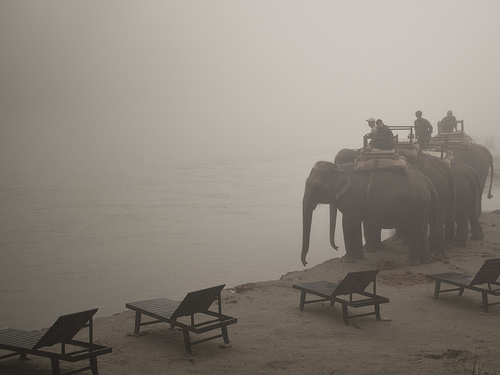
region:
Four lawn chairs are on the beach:
[25, 260, 491, 368]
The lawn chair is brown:
[253, 237, 388, 332]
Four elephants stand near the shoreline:
[304, 84, 485, 266]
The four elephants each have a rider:
[314, 90, 488, 272]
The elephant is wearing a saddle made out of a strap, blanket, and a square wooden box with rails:
[329, 110, 422, 222]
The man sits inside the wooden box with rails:
[321, 108, 404, 179]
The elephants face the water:
[83, 42, 458, 279]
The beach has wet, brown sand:
[185, 212, 477, 362]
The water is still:
[28, 48, 304, 271]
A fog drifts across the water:
[29, 19, 465, 239]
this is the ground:
[243, 297, 278, 371]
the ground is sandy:
[254, 297, 289, 367]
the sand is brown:
[248, 295, 283, 370]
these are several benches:
[5, 281, 236, 370]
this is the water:
[38, 218, 173, 288]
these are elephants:
[308, 105, 491, 260]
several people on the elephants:
[366, 111, 453, 163]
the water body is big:
[76, 70, 262, 241]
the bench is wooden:
[148, 297, 172, 311]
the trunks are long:
[300, 192, 337, 262]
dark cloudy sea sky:
[30, 42, 175, 192]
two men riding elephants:
[352, 109, 399, 149]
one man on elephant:
[411, 96, 433, 141]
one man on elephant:
[443, 113, 464, 131]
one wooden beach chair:
[8, 303, 130, 370]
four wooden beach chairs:
[19, 241, 494, 371]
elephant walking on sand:
[296, 161, 466, 250]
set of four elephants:
[336, 116, 498, 237]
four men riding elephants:
[354, 114, 481, 178]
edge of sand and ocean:
[228, 262, 303, 345]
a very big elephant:
[288, 149, 432, 269]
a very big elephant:
[371, 125, 473, 245]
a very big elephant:
[406, 115, 499, 228]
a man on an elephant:
[366, 117, 396, 152]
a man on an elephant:
[360, 112, 377, 134]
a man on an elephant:
[409, 106, 434, 143]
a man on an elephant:
[437, 102, 461, 134]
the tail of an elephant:
[485, 152, 498, 199]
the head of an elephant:
[296, 141, 336, 265]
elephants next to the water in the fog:
[29, 5, 493, 373]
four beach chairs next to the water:
[10, 251, 497, 362]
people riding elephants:
[289, 101, 493, 284]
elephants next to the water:
[283, 104, 493, 276]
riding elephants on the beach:
[281, 104, 498, 276]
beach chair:
[290, 266, 410, 340]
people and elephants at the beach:
[7, 59, 496, 373]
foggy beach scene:
[11, 9, 491, 357]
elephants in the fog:
[285, 90, 496, 288]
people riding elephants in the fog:
[285, 94, 496, 292]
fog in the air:
[27, 39, 474, 364]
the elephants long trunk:
[247, 116, 377, 314]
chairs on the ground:
[94, 266, 270, 366]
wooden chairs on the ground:
[106, 270, 313, 371]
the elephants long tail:
[421, 105, 498, 241]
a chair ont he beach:
[307, 275, 416, 356]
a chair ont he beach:
[113, 255, 190, 335]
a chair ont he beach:
[15, 292, 111, 367]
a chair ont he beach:
[438, 251, 493, 297]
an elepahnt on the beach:
[367, 130, 452, 239]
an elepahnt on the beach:
[437, 124, 481, 231]